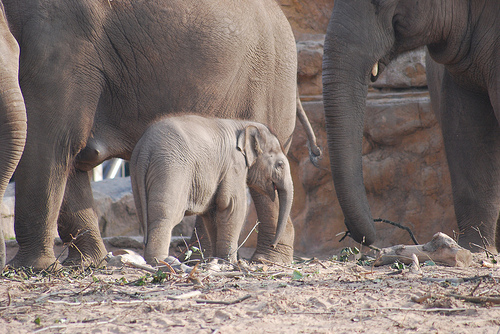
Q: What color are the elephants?
A: Gray.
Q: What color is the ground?
A: Brown.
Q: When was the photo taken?
A: Daytime.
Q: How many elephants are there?
A: More than two.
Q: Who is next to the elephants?
A: No one.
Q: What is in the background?
A: A wall.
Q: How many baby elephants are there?
A: One.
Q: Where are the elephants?
A: At a zoo.